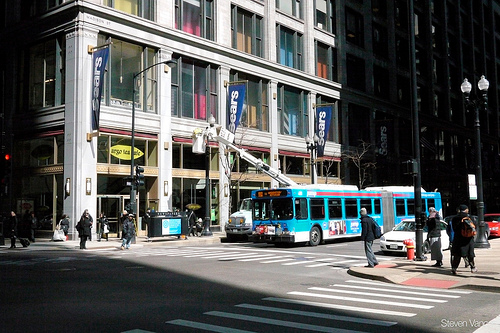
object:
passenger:
[355, 206, 384, 267]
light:
[474, 72, 491, 92]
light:
[459, 77, 475, 95]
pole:
[472, 95, 493, 248]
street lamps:
[458, 73, 496, 249]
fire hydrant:
[402, 235, 414, 258]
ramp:
[190, 124, 302, 191]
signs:
[84, 39, 117, 142]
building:
[23, 0, 343, 245]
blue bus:
[251, 181, 442, 248]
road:
[0, 238, 500, 332]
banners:
[225, 81, 247, 136]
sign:
[107, 142, 147, 162]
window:
[93, 130, 114, 167]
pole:
[407, 0, 424, 259]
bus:
[246, 184, 448, 246]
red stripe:
[317, 192, 408, 198]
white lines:
[284, 282, 438, 312]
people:
[447, 203, 478, 276]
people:
[425, 205, 447, 267]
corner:
[344, 252, 406, 285]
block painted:
[387, 272, 461, 291]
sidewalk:
[348, 236, 500, 287]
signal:
[84, 125, 105, 143]